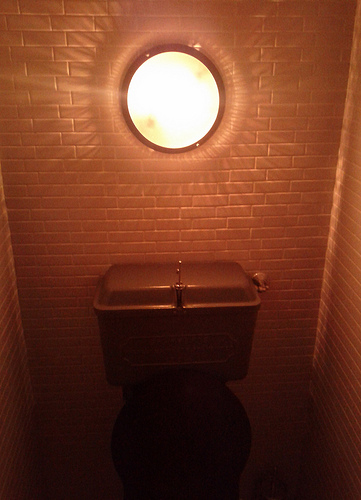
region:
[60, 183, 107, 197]
brick is next to brick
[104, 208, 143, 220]
brick is next to brick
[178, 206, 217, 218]
brick is next to brick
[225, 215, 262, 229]
brick is next to brick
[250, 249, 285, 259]
brick is next to brick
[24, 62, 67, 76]
brick is next to brick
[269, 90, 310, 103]
brick is next to brick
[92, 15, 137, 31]
brick is next to brick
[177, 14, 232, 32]
brick is next to brick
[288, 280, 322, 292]
brick is next to brick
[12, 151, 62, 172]
White bricks on a wall in a bathroom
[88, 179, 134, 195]
White bricks on a wall in a bathroom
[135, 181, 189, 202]
White bricks on a wall in a bathroom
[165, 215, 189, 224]
White bricks on a wall in a bathroom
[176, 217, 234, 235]
White bricks on a wall in a bathroom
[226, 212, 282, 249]
White bricks on a wall in a bathroom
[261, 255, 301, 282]
White bricks on a wall in a bathroom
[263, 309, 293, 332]
White bricks on a wall in a bathroom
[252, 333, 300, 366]
White bricks on a wall in a bathroom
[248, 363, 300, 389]
White bricks on a wall in a bathroom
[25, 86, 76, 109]
bricks of a wall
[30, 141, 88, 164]
bricks of a wall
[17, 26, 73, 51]
bricks of a wall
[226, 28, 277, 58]
bricks of a wall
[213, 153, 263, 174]
bricks of a wall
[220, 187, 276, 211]
bricks of a wall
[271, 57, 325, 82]
bricks of a wall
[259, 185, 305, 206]
bricks of a wall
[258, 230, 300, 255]
bricks of a wall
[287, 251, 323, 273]
bricks of a wall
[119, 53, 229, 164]
bright light behind toilet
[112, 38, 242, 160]
bright light on wall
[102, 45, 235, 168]
circle light on wall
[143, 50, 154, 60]
silver screw in light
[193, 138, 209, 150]
silver screw in light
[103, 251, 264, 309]
top of toilet back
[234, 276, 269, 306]
metal bar ont he wall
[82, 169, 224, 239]
white tile wall of bathroom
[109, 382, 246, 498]
toilet seat on toilet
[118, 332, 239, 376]
logo on back of toilet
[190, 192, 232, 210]
stone brick on a bathroom wall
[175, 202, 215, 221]
stone brick on a bathroom wall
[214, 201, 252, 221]
stone brick on a bathroom wall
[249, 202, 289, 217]
stone brick on a bathroom wall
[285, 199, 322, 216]
stone brick on a bathroom wall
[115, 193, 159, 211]
stone brick on a bathroom wall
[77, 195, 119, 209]
stone brick on a bathroom wall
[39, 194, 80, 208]
stone brick on a bathroom wall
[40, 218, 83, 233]
stone brick on a bathroom wall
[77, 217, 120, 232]
stone brick on a bathroom wall